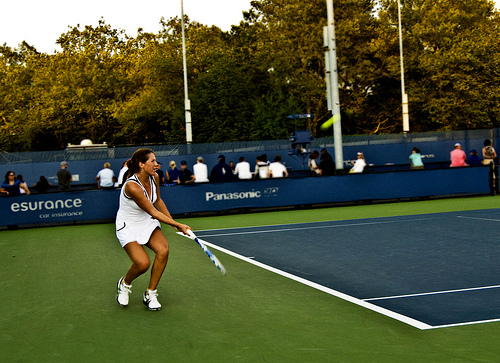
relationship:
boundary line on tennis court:
[178, 230, 426, 333] [174, 206, 497, 336]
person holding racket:
[104, 137, 191, 304] [183, 228, 227, 277]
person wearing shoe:
[114, 147, 192, 312] [116, 275, 131, 305]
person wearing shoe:
[114, 147, 192, 312] [141, 288, 161, 310]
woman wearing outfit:
[108, 143, 218, 314] [115, 175, 172, 249]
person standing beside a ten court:
[187, 151, 211, 189] [1, 191, 489, 359]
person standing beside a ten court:
[268, 153, 293, 185] [1, 191, 489, 359]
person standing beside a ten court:
[84, 159, 124, 190] [1, 191, 489, 359]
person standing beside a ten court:
[345, 146, 370, 176] [1, 191, 489, 359]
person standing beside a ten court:
[210, 153, 240, 185] [1, 191, 489, 359]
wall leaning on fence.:
[347, 113, 499, 166] [369, 166, 485, 204]